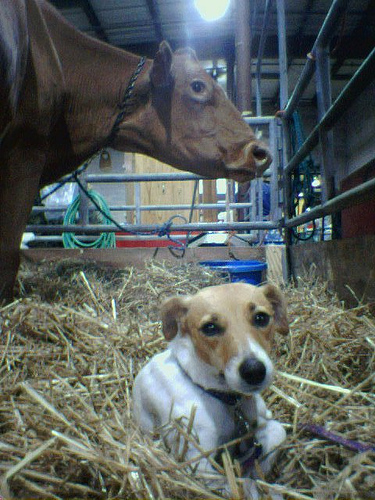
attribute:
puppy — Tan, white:
[114, 282, 317, 457]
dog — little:
[129, 277, 296, 491]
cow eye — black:
[186, 78, 214, 103]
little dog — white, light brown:
[131, 279, 291, 485]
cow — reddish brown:
[0, 0, 273, 306]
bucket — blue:
[185, 253, 278, 303]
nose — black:
[240, 359, 266, 383]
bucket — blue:
[148, 243, 274, 294]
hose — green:
[60, 188, 118, 252]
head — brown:
[157, 280, 285, 390]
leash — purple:
[296, 421, 371, 465]